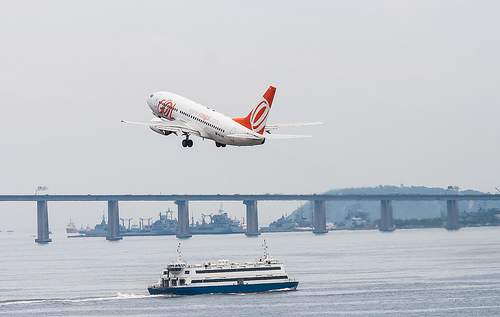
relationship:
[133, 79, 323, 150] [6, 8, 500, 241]
plane in sky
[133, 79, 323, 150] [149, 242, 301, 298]
plane flying over ship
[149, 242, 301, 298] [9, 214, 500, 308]
ship in river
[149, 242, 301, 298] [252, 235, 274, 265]
ship has antenna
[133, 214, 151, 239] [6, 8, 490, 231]
windmill in background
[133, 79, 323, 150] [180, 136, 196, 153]
plane has wheel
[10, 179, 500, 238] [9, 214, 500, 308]
bridge over river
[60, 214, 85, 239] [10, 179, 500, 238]
ship cruising toward bridge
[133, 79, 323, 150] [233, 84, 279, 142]
plane has tail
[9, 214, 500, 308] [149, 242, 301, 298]
river behind ship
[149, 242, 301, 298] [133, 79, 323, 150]
ship under plane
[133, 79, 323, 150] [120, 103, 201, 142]
plane has wing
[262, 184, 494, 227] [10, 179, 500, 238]
hill behind bridge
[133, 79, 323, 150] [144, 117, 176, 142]
plane has jet engine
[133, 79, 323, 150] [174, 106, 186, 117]
plane has window